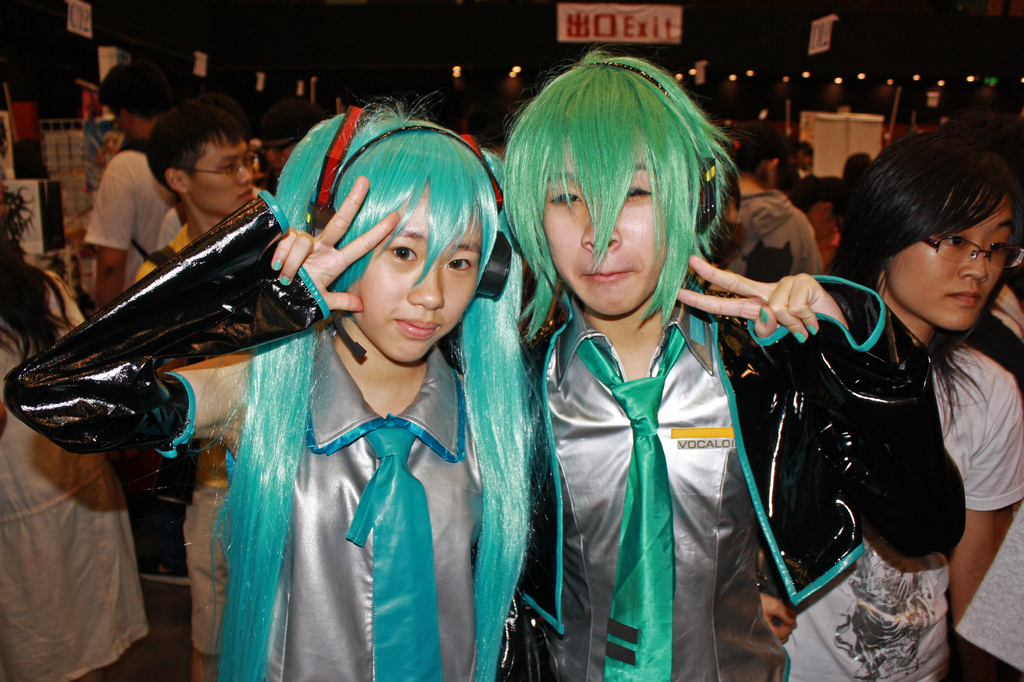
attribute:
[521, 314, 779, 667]
shirt — silver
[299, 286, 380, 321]
thumb — right hand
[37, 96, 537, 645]
person — blue haired